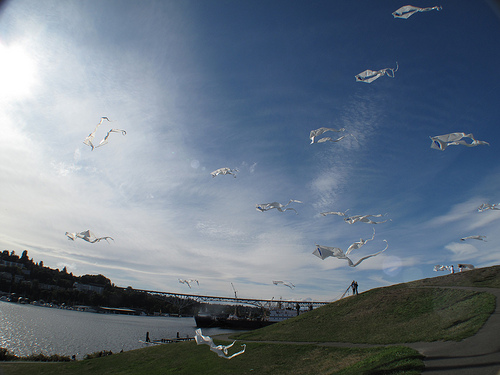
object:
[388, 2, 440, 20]
kite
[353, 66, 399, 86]
kite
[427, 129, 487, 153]
kite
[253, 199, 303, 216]
kite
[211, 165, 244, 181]
kite